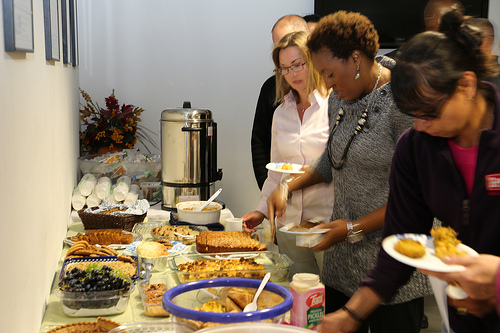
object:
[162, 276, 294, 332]
bowl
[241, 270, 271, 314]
spoon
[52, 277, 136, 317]
bowl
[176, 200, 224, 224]
dish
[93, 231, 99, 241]
bread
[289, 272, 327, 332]
bottle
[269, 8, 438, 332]
woman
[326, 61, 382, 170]
necklace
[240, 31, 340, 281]
woman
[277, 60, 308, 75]
glasses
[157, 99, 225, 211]
coffee dispenser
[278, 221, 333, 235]
plate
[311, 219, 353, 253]
hand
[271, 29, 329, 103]
hair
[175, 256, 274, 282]
food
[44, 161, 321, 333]
table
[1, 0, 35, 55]
pictures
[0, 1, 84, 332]
wall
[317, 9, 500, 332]
woman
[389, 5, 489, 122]
hair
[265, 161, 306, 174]
plate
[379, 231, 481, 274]
plate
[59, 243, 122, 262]
plate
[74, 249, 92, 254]
cookies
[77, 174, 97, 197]
stack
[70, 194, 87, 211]
cups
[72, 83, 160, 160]
bouqet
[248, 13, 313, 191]
man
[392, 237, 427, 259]
food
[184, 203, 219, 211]
casserole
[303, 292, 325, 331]
label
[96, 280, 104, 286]
berries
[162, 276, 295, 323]
rim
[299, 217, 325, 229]
food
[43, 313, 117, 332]
pie